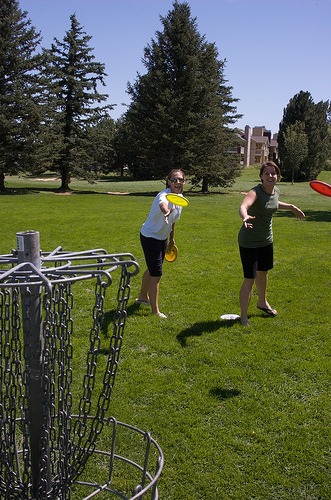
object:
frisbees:
[164, 191, 189, 208]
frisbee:
[307, 179, 330, 197]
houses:
[228, 126, 247, 168]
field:
[0, 160, 330, 499]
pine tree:
[30, 15, 118, 193]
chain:
[70, 278, 108, 464]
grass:
[0, 161, 330, 499]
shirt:
[138, 187, 184, 243]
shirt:
[236, 184, 280, 246]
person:
[237, 161, 306, 332]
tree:
[109, 0, 221, 182]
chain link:
[121, 283, 131, 303]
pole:
[8, 228, 48, 500]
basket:
[0, 413, 165, 498]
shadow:
[176, 317, 242, 350]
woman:
[135, 168, 186, 319]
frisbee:
[164, 241, 177, 263]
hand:
[167, 241, 176, 253]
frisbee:
[218, 311, 241, 326]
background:
[1, 1, 330, 499]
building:
[248, 134, 269, 166]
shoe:
[254, 301, 276, 319]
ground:
[0, 163, 330, 499]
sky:
[18, 0, 330, 142]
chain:
[1, 286, 13, 486]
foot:
[255, 297, 278, 317]